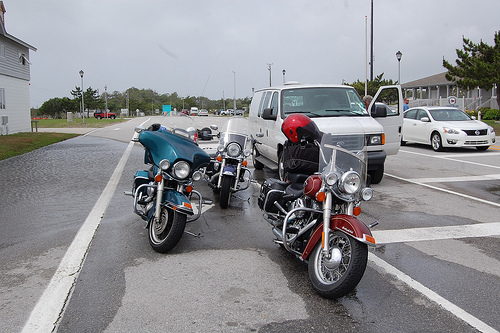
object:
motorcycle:
[123, 113, 221, 255]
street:
[0, 116, 497, 332]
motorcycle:
[256, 132, 379, 299]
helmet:
[280, 114, 319, 146]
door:
[365, 85, 405, 156]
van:
[246, 80, 405, 184]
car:
[395, 104, 494, 153]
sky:
[0, 1, 499, 101]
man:
[360, 96, 388, 118]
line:
[40, 115, 152, 331]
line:
[366, 250, 499, 333]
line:
[406, 174, 499, 185]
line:
[398, 148, 498, 168]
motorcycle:
[204, 116, 257, 210]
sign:
[160, 104, 174, 113]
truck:
[93, 109, 117, 118]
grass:
[0, 132, 78, 163]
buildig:
[0, 3, 38, 136]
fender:
[299, 213, 375, 263]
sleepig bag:
[283, 140, 320, 176]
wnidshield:
[316, 114, 369, 205]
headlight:
[337, 171, 363, 195]